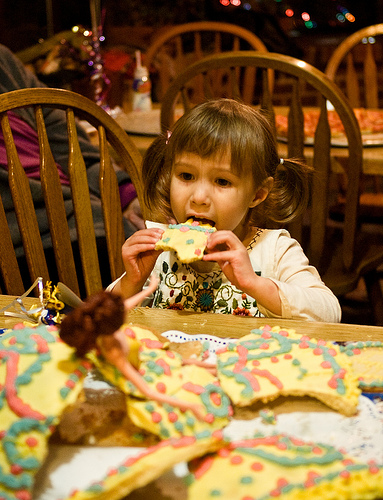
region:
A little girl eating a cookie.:
[106, 98, 346, 323]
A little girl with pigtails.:
[116, 96, 318, 239]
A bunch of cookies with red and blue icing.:
[10, 320, 377, 493]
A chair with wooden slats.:
[0, 141, 122, 272]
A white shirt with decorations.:
[110, 222, 341, 330]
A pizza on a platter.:
[259, 93, 379, 152]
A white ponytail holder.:
[273, 152, 292, 176]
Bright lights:
[220, 0, 357, 30]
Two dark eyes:
[169, 160, 237, 194]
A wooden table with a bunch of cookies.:
[2, 293, 381, 493]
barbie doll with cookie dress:
[54, 288, 330, 454]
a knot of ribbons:
[9, 266, 68, 328]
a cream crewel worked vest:
[151, 222, 283, 316]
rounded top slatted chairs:
[145, 15, 382, 111]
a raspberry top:
[0, 109, 139, 206]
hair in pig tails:
[118, 124, 330, 212]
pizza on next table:
[249, 82, 382, 167]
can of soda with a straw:
[131, 44, 160, 121]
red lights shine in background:
[211, 0, 369, 33]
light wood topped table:
[146, 302, 375, 339]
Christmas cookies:
[202, 317, 372, 423]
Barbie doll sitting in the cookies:
[54, 285, 243, 423]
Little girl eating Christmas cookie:
[103, 92, 346, 323]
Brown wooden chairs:
[0, 47, 367, 281]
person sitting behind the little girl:
[2, 16, 111, 291]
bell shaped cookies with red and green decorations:
[60, 424, 379, 496]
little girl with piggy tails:
[134, 95, 328, 228]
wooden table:
[0, 304, 378, 392]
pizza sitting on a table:
[266, 102, 377, 148]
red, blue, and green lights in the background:
[230, 0, 381, 33]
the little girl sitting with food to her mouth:
[106, 95, 342, 320]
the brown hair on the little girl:
[139, 95, 302, 228]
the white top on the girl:
[112, 222, 345, 324]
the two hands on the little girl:
[109, 223, 255, 290]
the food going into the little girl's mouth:
[159, 211, 216, 261]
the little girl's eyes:
[172, 164, 235, 190]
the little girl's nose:
[185, 176, 215, 207]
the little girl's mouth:
[176, 209, 216, 231]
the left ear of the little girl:
[248, 176, 271, 208]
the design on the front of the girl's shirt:
[155, 260, 258, 314]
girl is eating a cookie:
[165, 221, 210, 259]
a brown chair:
[234, 55, 296, 102]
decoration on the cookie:
[229, 354, 285, 387]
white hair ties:
[278, 151, 286, 165]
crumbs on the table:
[173, 315, 217, 330]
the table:
[304, 322, 345, 336]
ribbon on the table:
[6, 290, 32, 316]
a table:
[158, 38, 196, 54]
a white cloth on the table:
[291, 399, 339, 434]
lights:
[276, 7, 323, 31]